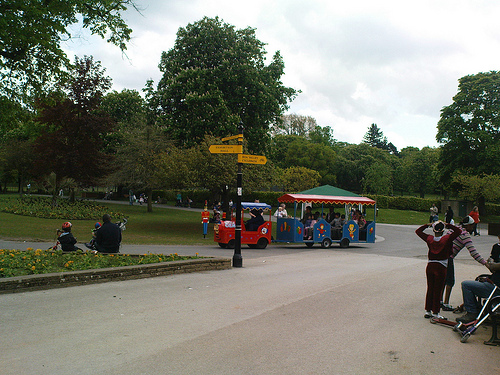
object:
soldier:
[200, 200, 209, 239]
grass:
[142, 203, 199, 237]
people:
[91, 214, 122, 253]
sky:
[0, 0, 500, 154]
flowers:
[5, 248, 89, 266]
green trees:
[0, 0, 498, 207]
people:
[57, 221, 83, 252]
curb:
[22, 257, 233, 291]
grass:
[36, 258, 88, 271]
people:
[299, 205, 369, 241]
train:
[214, 185, 378, 249]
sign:
[238, 154, 267, 165]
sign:
[209, 145, 243, 154]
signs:
[221, 134, 243, 142]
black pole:
[233, 164, 243, 267]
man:
[414, 220, 463, 320]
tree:
[139, 15, 302, 157]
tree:
[435, 70, 497, 216]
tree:
[359, 120, 394, 152]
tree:
[1, 0, 151, 135]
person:
[469, 206, 481, 237]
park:
[3, 3, 498, 373]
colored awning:
[277, 184, 376, 206]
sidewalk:
[0, 283, 422, 375]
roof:
[278, 184, 377, 203]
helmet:
[61, 221, 72, 230]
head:
[62, 221, 73, 232]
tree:
[356, 126, 405, 194]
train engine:
[213, 202, 273, 250]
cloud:
[0, 12, 500, 154]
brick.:
[105, 268, 139, 280]